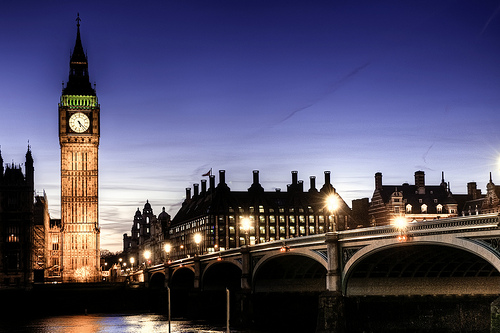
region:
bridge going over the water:
[129, 208, 499, 330]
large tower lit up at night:
[59, 11, 100, 283]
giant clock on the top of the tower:
[66, 111, 92, 136]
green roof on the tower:
[56, 7, 102, 110]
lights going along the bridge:
[101, 151, 499, 281]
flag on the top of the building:
[200, 166, 216, 181]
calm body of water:
[3, 278, 376, 332]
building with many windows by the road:
[119, 166, 366, 276]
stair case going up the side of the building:
[29, 212, 54, 279]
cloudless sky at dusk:
[3, 0, 499, 256]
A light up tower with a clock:
[49, 8, 114, 287]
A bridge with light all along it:
[114, 206, 498, 332]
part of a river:
[14, 303, 249, 330]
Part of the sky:
[136, 115, 419, 165]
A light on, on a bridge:
[314, 188, 342, 222]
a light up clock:
[66, 109, 91, 135]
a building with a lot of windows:
[165, 167, 353, 259]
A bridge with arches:
[143, 216, 487, 321]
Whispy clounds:
[92, 181, 135, 249]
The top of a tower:
[48, 7, 105, 96]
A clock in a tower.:
[65, 109, 92, 134]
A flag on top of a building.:
[202, 166, 214, 179]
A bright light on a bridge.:
[390, 210, 410, 235]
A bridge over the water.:
[131, 209, 498, 330]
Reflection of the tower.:
[57, 310, 117, 330]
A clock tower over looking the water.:
[49, 10, 104, 279]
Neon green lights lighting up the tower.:
[62, 92, 96, 106]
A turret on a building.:
[444, 182, 457, 217]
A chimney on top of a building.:
[246, 168, 262, 192]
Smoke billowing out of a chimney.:
[417, 144, 438, 171]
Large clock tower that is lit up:
[47, 30, 119, 315]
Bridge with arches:
[134, 218, 495, 293]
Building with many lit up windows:
[176, 170, 368, 262]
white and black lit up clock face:
[67, 109, 95, 134]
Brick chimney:
[392, 162, 430, 191]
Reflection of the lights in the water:
[127, 308, 175, 330]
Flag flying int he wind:
[190, 157, 215, 185]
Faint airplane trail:
[256, 52, 373, 147]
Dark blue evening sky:
[26, 15, 490, 105]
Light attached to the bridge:
[139, 247, 156, 262]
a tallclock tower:
[3, 60, 115, 251]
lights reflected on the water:
[32, 298, 167, 332]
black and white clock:
[67, 114, 94, 130]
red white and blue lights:
[31, 311, 146, 330]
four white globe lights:
[124, 225, 205, 274]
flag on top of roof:
[165, 158, 235, 208]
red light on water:
[54, 296, 101, 330]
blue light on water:
[108, 309, 122, 331]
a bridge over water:
[65, 198, 460, 330]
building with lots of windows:
[145, 163, 346, 278]